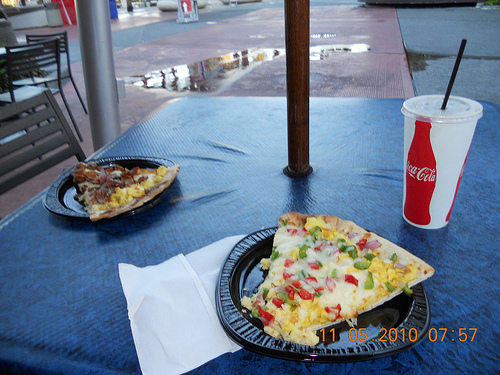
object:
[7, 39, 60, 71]
slats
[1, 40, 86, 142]
chair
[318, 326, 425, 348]
date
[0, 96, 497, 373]
table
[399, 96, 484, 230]
cup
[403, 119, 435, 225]
coca-cola logo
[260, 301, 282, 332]
tomato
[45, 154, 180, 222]
plate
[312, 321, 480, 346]
stamp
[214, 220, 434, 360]
plate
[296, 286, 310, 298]
tomato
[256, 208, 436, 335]
pizza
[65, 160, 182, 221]
pizza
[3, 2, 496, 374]
table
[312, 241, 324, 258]
tomato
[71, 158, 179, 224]
slice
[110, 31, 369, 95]
water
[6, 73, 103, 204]
slats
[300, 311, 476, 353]
print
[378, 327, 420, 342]
print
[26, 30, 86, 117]
chair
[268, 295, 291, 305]
tomato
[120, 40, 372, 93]
puddle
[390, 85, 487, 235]
drink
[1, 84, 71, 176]
back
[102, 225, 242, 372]
napkin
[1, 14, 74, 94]
background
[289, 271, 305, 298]
tomato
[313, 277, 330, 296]
tomato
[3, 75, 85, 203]
chair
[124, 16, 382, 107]
ground